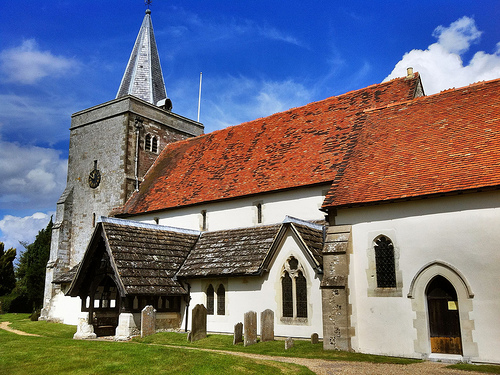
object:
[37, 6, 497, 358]
church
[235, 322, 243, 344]
headstone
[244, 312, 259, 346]
headstone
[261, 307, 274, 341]
headstone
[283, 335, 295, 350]
headstone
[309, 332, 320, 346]
headstone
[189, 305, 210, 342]
headstone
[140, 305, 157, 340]
headstone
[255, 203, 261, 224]
window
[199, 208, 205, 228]
window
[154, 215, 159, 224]
window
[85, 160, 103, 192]
clock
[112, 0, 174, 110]
steeple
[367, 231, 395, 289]
window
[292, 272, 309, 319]
window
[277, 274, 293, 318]
window